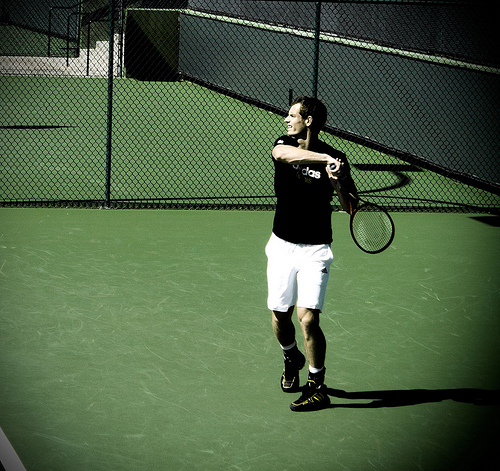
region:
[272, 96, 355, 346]
this is a man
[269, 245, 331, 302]
this is a short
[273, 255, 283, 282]
the short is white in color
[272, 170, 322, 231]
this is a t shirt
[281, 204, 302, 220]
the t shirt is black in color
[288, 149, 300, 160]
the man is light skinned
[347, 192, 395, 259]
this is a racket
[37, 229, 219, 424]
this is the playing ground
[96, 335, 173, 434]
the ground is green in color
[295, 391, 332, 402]
this is a sport shoe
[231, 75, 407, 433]
a man playing tennis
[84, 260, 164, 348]
the tennis court is green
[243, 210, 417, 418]
he has white shorts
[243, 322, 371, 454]
he is wearing socks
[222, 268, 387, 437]
his shoes have a yellow stripe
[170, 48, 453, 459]
he has a tennis racket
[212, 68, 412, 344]
the adidas logo is white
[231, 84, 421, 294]
the shirt is by adidas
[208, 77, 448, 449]
he is casting a shadow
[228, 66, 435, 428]
the shirt is black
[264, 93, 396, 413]
A man playing tennis.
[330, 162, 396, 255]
A black tennis racket.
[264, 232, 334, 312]
A pair of white shorts.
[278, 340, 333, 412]
A pair of shoes and socks.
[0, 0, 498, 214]
A black chain link fence.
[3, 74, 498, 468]
A green tennis court.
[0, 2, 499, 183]
A green back wall.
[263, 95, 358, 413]
A man in white shorts.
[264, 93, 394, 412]
A man with a racket.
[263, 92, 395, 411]
A man swinging a racket.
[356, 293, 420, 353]
part of a court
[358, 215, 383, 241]
part of a racket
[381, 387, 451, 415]
part of a shae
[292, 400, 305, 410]
part of a shoe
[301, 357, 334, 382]
part of a sock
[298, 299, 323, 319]
edge of a short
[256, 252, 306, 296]
part of a short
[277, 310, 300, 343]
part of a leg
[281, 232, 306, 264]
part of a lace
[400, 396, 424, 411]
edge of a shade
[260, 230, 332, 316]
the man is wearing white shorts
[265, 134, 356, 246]
the man is wearing a white shirt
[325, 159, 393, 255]
the man is holding a tennis racket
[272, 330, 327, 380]
the man is wearing white socks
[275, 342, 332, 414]
the man is wearing black tennis shoes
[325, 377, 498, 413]
the man's shadow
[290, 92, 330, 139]
the man has brown hair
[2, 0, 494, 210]
the fence is made of metal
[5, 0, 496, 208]
the fence is chain link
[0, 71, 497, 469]
the tennis court is green